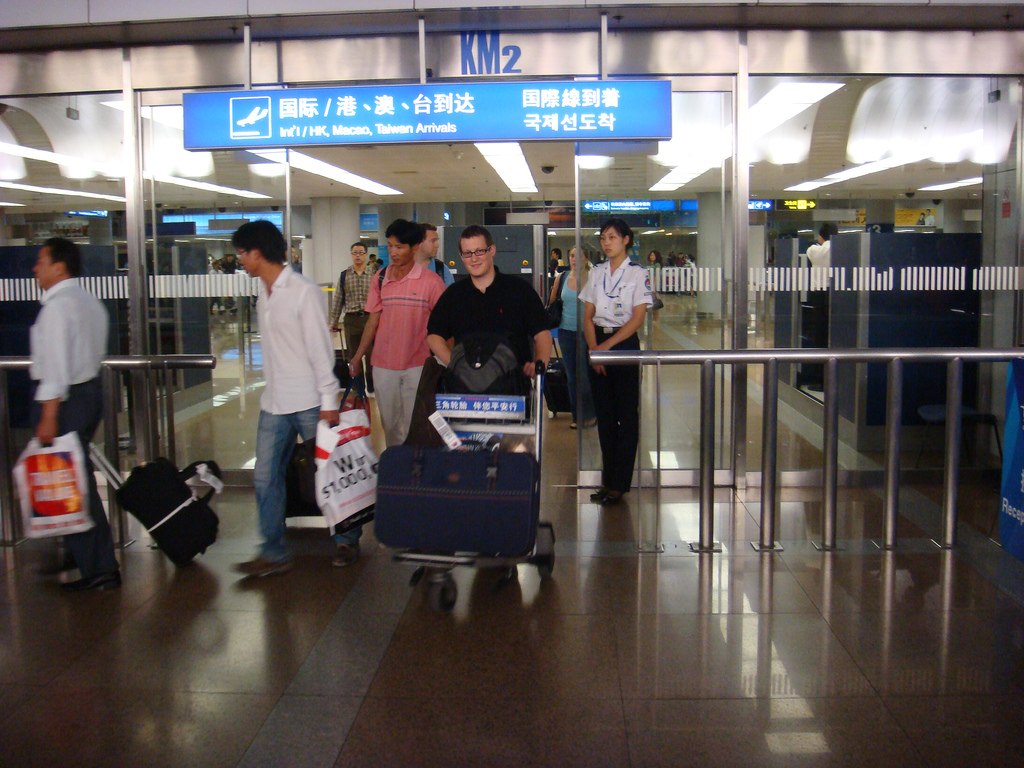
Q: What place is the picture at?
A: It is at the airport.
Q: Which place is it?
A: It is an airport.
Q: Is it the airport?
A: Yes, it is the airport.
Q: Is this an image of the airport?
A: Yes, it is showing the airport.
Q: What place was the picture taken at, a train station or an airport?
A: It was taken at an airport.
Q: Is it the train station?
A: No, it is the airport.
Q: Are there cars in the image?
A: No, there are no cars.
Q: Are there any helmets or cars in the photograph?
A: No, there are no cars or helmets.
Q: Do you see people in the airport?
A: Yes, there is a person in the airport.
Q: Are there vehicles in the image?
A: No, there are no vehicles.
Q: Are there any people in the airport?
A: Yes, there is a person in the airport.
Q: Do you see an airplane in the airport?
A: No, there is a person in the airport.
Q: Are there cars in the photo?
A: No, there are no cars.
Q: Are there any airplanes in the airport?
A: No, there is a person in the airport.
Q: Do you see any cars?
A: No, there are no cars.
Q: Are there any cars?
A: No, there are no cars.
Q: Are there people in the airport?
A: Yes, there is a person in the airport.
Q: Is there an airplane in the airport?
A: No, there is a person in the airport.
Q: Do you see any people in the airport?
A: Yes, there is a person in the airport.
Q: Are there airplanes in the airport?
A: No, there is a person in the airport.